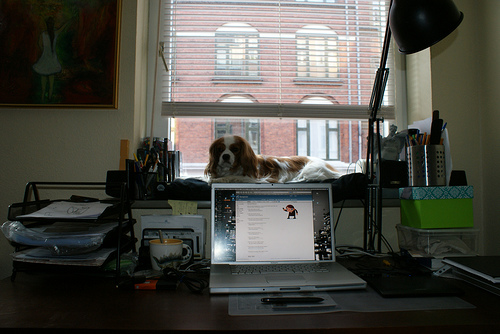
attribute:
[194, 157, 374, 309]
laptop —  computer,  on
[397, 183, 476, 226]
box — green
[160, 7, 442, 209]
building —  red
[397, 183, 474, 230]
box —  green and blue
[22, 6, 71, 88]
girl —  little,  a picture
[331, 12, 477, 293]
lamp — desk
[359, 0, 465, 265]
desk lamp — off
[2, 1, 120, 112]
picture — framed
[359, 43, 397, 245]
desk lamp — extendable 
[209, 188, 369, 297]
laptop — grey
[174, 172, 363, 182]
seal —  window's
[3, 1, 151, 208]
wall — white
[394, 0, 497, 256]
wall — white